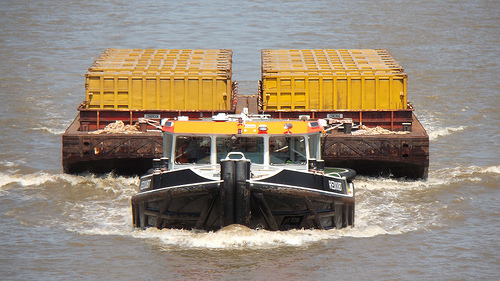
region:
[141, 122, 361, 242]
a tugboat pulling stuff in the water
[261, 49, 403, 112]
a line of yellow containers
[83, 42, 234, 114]
another bunch of yellow containers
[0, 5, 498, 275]
a large body of water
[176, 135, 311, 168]
the windows of the boat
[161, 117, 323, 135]
the top of the boat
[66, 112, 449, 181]
the boat holding the yellow containers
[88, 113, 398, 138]
random items in the front of the boat.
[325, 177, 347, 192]
writing on the side of the boat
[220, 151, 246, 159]
a little hook on the boat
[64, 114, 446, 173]
a barge floating on the ocean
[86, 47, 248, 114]
a large yellow shipping container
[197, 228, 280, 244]
white waves in the water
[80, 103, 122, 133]
red supports under a container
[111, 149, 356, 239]
a shipping lift sitting in the ocean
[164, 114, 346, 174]
a cargo boat behind a lift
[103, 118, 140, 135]
a long woven rope on the deck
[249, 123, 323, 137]
safety lights on the roof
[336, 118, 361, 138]
a black barrel on the floor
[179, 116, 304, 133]
a yellow roof on a boat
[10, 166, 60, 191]
whitecaps in the ocean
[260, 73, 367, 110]
rectangular shipping container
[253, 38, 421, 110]
large shipping containers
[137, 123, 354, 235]
barge to tow shipping containers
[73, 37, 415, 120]
two large yellow metal shipping containers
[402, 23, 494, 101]
open ocean water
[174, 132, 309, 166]
main bridge area of barge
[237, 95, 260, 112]
person on deck of tubgoat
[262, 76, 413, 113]
thirteen yellow squares and rectangles wide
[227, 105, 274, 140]
Radar post on top of bridge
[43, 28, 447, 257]
This is a barge.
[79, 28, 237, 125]
These are the left containers.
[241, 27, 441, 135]
These are the right containers.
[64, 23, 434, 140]
These are yellow containers.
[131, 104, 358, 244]
This is a boat.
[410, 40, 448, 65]
This is the water.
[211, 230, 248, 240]
This is water spray.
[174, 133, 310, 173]
This is a windshield.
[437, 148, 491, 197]
This is a wave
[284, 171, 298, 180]
This is the color black.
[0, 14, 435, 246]
Large boat in the water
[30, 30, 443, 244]
Large barge style boat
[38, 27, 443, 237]
large barge style boat in the water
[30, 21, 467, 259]
Boat moving through the water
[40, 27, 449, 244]
Large boat with yellow containers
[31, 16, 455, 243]
Large boat pulling containers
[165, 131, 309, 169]
Boat windshield made of glass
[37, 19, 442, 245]
Large boat pulling containers in the water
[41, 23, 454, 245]
Black boat pulling yellow containers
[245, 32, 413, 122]
Yellow storage container